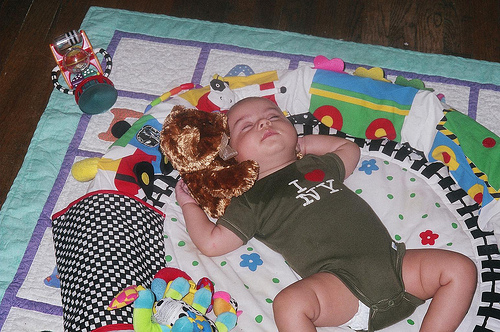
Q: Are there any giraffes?
A: No, there are no giraffes.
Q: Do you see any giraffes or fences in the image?
A: No, there are no giraffes or fences.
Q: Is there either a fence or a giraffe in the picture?
A: No, there are no giraffes or fences.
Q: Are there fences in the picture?
A: No, there are no fences.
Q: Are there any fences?
A: No, there are no fences.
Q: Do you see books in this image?
A: No, there are no books.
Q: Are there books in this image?
A: No, there are no books.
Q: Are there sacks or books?
A: No, there are no books or sacks.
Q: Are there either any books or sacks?
A: No, there are no books or sacks.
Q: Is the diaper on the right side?
A: Yes, the diaper is on the right of the image.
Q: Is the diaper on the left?
A: No, the diaper is on the right of the image.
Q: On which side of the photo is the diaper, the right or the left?
A: The diaper is on the right of the image.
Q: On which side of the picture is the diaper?
A: The diaper is on the right of the image.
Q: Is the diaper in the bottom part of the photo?
A: Yes, the diaper is in the bottom of the image.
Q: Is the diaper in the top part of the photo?
A: No, the diaper is in the bottom of the image.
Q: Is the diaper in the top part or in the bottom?
A: The diaper is in the bottom of the image.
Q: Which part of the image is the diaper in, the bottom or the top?
A: The diaper is in the bottom of the image.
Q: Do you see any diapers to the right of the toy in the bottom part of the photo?
A: Yes, there is a diaper to the right of the toy.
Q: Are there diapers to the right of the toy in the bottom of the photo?
A: Yes, there is a diaper to the right of the toy.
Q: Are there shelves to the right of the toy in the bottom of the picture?
A: No, there is a diaper to the right of the toy.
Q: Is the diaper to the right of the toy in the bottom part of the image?
A: Yes, the diaper is to the right of the toy.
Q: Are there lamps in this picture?
A: No, there are no lamps.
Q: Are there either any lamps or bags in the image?
A: No, there are no lamps or bags.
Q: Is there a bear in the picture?
A: Yes, there is a bear.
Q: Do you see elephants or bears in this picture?
A: Yes, there is a bear.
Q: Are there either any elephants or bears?
A: Yes, there is a bear.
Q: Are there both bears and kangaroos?
A: No, there is a bear but no kangaroos.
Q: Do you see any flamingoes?
A: No, there are no flamingoes.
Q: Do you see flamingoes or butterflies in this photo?
A: No, there are no flamingoes or butterflies.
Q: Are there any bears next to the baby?
A: Yes, there is a bear next to the baby.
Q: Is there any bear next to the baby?
A: Yes, there is a bear next to the baby.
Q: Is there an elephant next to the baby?
A: No, there is a bear next to the baby.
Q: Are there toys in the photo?
A: Yes, there is a toy.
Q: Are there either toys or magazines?
A: Yes, there is a toy.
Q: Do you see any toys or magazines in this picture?
A: Yes, there is a toy.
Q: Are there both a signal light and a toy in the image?
A: No, there is a toy but no traffic lights.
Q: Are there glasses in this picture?
A: No, there are no glasses.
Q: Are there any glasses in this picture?
A: No, there are no glasses.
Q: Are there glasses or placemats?
A: No, there are no glasses or placemats.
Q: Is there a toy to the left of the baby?
A: Yes, there is a toy to the left of the baby.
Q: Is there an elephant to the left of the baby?
A: No, there is a toy to the left of the baby.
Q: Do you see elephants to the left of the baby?
A: No, there is a toy to the left of the baby.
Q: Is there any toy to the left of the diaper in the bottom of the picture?
A: Yes, there is a toy to the left of the diaper.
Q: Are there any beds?
A: Yes, there is a bed.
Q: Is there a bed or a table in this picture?
A: Yes, there is a bed.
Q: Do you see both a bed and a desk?
A: No, there is a bed but no desks.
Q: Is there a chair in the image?
A: No, there are no chairs.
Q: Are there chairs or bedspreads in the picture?
A: No, there are no chairs or bedspreads.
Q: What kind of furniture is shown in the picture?
A: The furniture is a bed.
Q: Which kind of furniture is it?
A: The piece of furniture is a bed.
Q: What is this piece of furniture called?
A: This is a bed.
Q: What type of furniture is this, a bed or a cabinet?
A: This is a bed.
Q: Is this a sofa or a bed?
A: This is a bed.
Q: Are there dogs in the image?
A: No, there are no dogs.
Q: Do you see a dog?
A: No, there are no dogs.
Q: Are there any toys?
A: Yes, there is a toy.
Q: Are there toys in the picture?
A: Yes, there is a toy.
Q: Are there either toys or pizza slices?
A: Yes, there is a toy.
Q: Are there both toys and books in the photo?
A: No, there is a toy but no books.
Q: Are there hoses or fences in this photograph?
A: No, there are no fences or hoses.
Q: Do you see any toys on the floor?
A: Yes, there is a toy on the floor.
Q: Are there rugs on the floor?
A: No, there is a toy on the floor.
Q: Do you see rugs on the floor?
A: No, there is a toy on the floor.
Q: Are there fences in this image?
A: No, there are no fences.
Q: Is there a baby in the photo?
A: Yes, there is a baby.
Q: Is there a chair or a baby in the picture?
A: Yes, there is a baby.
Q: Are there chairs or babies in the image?
A: Yes, there is a baby.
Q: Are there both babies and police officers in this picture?
A: No, there is a baby but no policemen.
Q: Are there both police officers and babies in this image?
A: No, there is a baby but no policemen.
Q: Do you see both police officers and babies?
A: No, there is a baby but no policemen.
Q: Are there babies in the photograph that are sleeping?
A: Yes, there is a baby that is sleeping.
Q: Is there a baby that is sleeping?
A: Yes, there is a baby that is sleeping.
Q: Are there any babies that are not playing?
A: Yes, there is a baby that is sleeping.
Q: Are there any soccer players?
A: No, there are no soccer players.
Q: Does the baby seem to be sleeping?
A: Yes, the baby is sleeping.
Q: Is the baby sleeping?
A: Yes, the baby is sleeping.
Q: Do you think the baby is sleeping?
A: Yes, the baby is sleeping.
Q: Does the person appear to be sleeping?
A: Yes, the baby is sleeping.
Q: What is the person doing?
A: The baby is sleeping.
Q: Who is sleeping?
A: The baby is sleeping.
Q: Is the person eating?
A: No, the baby is sleeping.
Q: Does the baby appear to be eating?
A: No, the baby is sleeping.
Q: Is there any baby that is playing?
A: No, there is a baby but he is sleeping.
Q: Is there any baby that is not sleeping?
A: No, there is a baby but he is sleeping.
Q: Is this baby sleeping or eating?
A: The baby is sleeping.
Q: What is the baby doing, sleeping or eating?
A: The baby is sleeping.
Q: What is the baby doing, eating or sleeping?
A: The baby is sleeping.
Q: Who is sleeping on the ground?
A: The baby is sleeping on the ground.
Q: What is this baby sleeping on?
A: The baby is sleeping on the ground.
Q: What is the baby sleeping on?
A: The baby is sleeping on the ground.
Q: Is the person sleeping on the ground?
A: Yes, the baby is sleeping on the ground.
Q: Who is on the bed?
A: The baby is on the bed.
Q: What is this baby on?
A: The baby is on the bed.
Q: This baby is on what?
A: The baby is on the bed.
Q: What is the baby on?
A: The baby is on the bed.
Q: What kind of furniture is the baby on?
A: The baby is on the bed.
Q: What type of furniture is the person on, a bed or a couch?
A: The baby is on a bed.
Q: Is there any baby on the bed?
A: Yes, there is a baby on the bed.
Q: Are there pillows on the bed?
A: No, there is a baby on the bed.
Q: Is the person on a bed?
A: Yes, the baby is on a bed.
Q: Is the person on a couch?
A: No, the baby is on a bed.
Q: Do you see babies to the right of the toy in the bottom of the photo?
A: Yes, there is a baby to the right of the toy.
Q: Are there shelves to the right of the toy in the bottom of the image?
A: No, there is a baby to the right of the toy.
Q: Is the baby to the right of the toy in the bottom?
A: Yes, the baby is to the right of the toy.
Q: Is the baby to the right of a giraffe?
A: No, the baby is to the right of the toy.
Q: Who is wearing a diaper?
A: The baby is wearing a diaper.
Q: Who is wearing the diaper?
A: The baby is wearing a diaper.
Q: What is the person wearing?
A: The baby is wearing a diaper.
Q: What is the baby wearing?
A: The baby is wearing a diaper.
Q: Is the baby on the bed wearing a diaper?
A: Yes, the baby is wearing a diaper.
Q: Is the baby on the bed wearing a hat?
A: No, the baby is wearing a diaper.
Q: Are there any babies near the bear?
A: Yes, there is a baby near the bear.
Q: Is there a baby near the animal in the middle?
A: Yes, there is a baby near the bear.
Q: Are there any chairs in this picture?
A: No, there are no chairs.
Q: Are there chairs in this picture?
A: No, there are no chairs.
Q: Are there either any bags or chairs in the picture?
A: No, there are no chairs or bags.